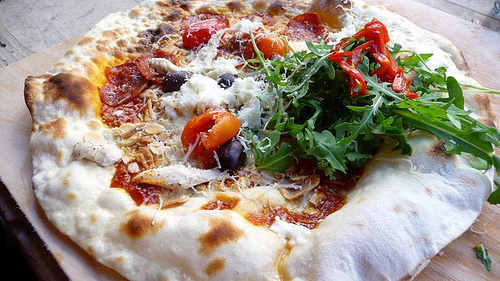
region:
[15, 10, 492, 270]
A home made pzza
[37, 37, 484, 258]
the pizza has topings on it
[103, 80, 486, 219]
the pizza is on a pizza plate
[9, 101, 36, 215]
the plate is made of wood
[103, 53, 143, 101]
the pizza has pepperoni on it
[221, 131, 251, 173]
the pizza has olives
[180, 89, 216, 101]
the pizza has cheese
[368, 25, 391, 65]
the pizza has red pepper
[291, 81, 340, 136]
the pizza has argula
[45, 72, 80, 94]
the pizza is slightly burnt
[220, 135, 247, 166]
topping on the pizza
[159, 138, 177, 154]
topping on the pizza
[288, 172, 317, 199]
topping on the pizza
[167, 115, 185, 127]
topping on the pizza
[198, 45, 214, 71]
topping on the pizza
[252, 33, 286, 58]
topping on the pizza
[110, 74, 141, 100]
topping on the pizza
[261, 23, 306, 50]
topping on the pizza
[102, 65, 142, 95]
topping on the pizza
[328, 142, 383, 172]
topping on the pizza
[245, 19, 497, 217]
green vegetables on pizza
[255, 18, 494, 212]
green vegetables have leafs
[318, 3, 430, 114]
red vegetable on green vegetables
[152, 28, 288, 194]
white cheese on pizza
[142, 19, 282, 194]
white cheese is shredded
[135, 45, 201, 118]
black olives on pizza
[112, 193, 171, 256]
pizza has brown spot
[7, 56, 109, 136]
pizza crust has bubble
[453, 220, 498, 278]
green vegetable on table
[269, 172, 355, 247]
red sauce on pizza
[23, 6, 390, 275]
a cooked pizza on atbale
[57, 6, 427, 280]
a baked pizza on a table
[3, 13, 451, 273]
a table with a pizza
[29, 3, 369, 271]
a pizza on a table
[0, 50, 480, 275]
a table with a cooked pizza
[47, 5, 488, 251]
a table with a baked pizza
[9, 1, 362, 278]
sauce on a pizza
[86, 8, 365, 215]
red sauce on a pizza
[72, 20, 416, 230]
cheese on a pizza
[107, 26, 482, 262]
metled cheese on a pizza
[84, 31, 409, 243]
Pizza with vegetables and meat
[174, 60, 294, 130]
Pizza with cheese on top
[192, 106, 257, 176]
Pizza with olive on top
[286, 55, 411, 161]
pizza with vegetable on top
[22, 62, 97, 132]
pizza with a burnt end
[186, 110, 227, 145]
Pizza with a tomato on it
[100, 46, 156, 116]
pizza with pepperoni on it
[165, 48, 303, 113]
pizza with grated cheese on top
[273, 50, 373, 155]
Pizza with spinach on top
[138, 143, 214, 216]
Pizza with meat on it